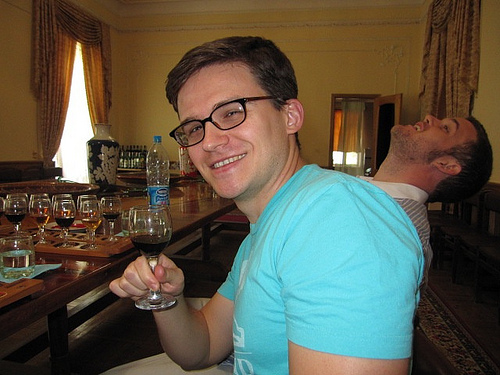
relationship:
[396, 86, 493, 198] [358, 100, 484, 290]
head of a man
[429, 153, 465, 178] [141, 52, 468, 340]
ear of a man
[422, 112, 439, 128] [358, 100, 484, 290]
nose of a man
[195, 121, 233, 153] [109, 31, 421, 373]
nose of a man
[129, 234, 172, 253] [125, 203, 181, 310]
wine in a glass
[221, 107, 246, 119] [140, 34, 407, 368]
eye of man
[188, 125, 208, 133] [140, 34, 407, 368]
eye of man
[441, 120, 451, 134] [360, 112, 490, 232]
eye of man